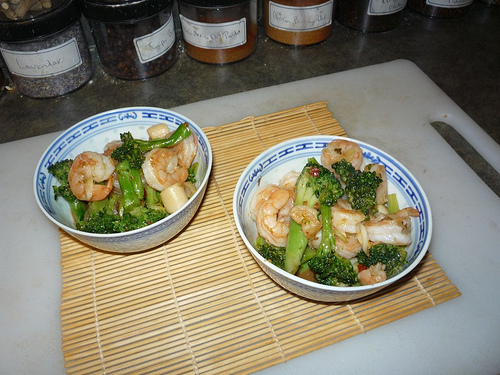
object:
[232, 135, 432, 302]
bowl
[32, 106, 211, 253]
bowl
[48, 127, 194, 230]
food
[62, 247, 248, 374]
place mat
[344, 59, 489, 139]
cutting board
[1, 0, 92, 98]
containers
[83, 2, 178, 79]
spices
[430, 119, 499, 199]
handle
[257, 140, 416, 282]
food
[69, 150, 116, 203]
shrimp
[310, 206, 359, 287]
broccoli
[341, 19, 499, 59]
counter top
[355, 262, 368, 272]
red pepper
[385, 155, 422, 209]
blue on the rim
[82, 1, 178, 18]
top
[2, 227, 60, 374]
plastic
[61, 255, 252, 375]
mat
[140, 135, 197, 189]
sea food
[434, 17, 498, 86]
dark granite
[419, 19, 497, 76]
counter top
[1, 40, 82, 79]
label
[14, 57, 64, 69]
lavender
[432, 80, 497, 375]
cutting board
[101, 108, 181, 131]
rim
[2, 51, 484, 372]
table